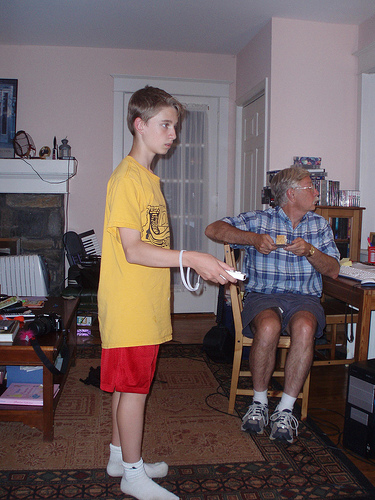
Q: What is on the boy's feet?
A: Socks.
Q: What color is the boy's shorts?
A: Red.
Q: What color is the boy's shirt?
A: Yellow.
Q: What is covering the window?
A: A curtain.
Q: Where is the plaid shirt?
A: On the man.